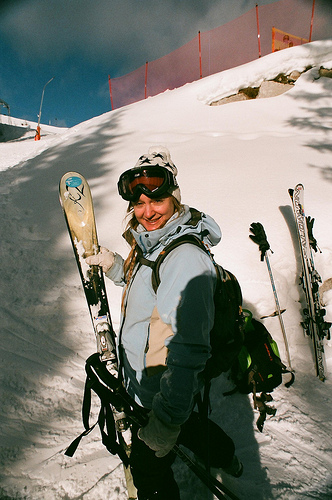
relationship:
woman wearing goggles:
[86, 149, 220, 500] [118, 166, 175, 202]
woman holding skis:
[86, 149, 220, 500] [60, 170, 145, 499]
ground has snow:
[1, 40, 331, 500] [1, 39, 332, 500]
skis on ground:
[286, 183, 326, 381] [1, 40, 331, 500]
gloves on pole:
[249, 223, 275, 261] [263, 254, 294, 373]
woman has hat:
[86, 149, 220, 500] [134, 146, 181, 199]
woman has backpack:
[86, 149, 220, 500] [153, 234, 243, 386]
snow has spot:
[1, 39, 332, 500] [70, 374, 76, 382]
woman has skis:
[86, 149, 220, 500] [60, 170, 145, 499]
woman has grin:
[86, 149, 220, 500] [141, 214, 162, 224]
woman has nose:
[86, 149, 220, 500] [144, 204, 155, 220]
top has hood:
[106, 205, 222, 432] [188, 207, 224, 249]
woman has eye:
[86, 149, 220, 500] [149, 197, 165, 204]